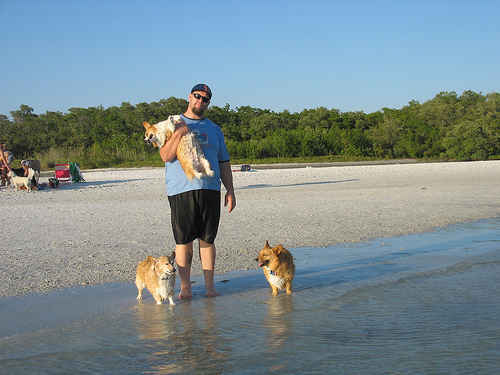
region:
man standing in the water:
[136, 65, 248, 315]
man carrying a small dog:
[137, 76, 243, 312]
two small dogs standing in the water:
[116, 233, 327, 308]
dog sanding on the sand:
[6, 168, 46, 193]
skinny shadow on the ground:
[240, 174, 357, 191]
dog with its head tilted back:
[138, 112, 212, 189]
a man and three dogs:
[106, 72, 326, 315]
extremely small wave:
[336, 242, 486, 317]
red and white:
[53, 157, 75, 187]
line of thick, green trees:
[3, 88, 498, 176]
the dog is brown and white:
[140, 270, 160, 292]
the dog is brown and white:
[149, 268, 157, 286]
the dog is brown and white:
[143, 283, 163, 302]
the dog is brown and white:
[151, 278, 166, 285]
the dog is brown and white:
[147, 271, 166, 302]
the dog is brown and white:
[149, 276, 155, 296]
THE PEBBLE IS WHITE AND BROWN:
[42, 244, 61, 264]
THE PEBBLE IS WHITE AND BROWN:
[82, 272, 84, 276]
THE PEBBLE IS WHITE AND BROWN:
[62, 252, 75, 262]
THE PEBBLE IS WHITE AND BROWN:
[53, 220, 118, 294]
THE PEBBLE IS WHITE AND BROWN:
[86, 263, 102, 273]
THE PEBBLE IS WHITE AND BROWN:
[76, 264, 93, 271]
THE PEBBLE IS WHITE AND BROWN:
[87, 265, 102, 279]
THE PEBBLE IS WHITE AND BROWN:
[74, 258, 88, 268]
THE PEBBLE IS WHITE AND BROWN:
[104, 250, 116, 259]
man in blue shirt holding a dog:
[142, 81, 238, 304]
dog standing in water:
[250, 236, 298, 298]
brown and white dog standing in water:
[132, 249, 182, 316]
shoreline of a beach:
[1, 205, 498, 373]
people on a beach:
[3, 143, 91, 198]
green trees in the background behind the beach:
[0, 85, 499, 178]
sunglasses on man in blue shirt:
[191, 91, 209, 103]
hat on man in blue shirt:
[188, 78, 215, 95]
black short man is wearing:
[163, 183, 229, 245]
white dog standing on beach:
[8, 168, 36, 195]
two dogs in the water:
[114, 242, 316, 307]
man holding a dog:
[138, 78, 241, 301]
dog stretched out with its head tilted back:
[129, 111, 223, 184]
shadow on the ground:
[240, 168, 357, 201]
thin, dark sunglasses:
[189, 91, 213, 104]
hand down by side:
[222, 181, 238, 216]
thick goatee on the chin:
[192, 105, 205, 116]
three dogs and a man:
[96, 76, 318, 308]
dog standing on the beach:
[7, 168, 38, 191]